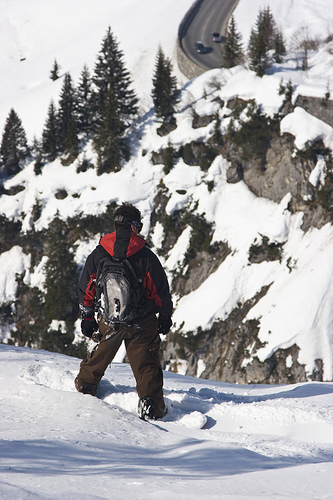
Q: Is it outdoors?
A: Yes, it is outdoors.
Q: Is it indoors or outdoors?
A: It is outdoors.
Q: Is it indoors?
A: No, it is outdoors.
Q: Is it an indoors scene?
A: No, it is outdoors.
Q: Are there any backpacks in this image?
A: Yes, there is a backpack.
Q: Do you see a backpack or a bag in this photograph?
A: Yes, there is a backpack.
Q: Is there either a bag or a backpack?
A: Yes, there is a backpack.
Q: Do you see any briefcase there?
A: No, there are no briefcases.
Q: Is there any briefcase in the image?
A: No, there are no briefcases.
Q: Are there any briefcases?
A: No, there are no briefcases.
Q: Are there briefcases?
A: No, there are no briefcases.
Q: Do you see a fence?
A: No, there are no fences.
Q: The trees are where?
A: The trees are on the mountain.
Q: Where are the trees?
A: The trees are on the mountain.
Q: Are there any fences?
A: No, there are no fences.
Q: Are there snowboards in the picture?
A: Yes, there is a snowboard.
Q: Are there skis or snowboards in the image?
A: Yes, there is a snowboard.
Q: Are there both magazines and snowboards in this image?
A: No, there is a snowboard but no magazines.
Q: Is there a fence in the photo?
A: No, there are no fences.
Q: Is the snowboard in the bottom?
A: Yes, the snowboard is in the bottom of the image.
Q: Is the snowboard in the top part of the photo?
A: No, the snowboard is in the bottom of the image.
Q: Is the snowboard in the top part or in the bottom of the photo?
A: The snowboard is in the bottom of the image.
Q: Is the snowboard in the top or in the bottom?
A: The snowboard is in the bottom of the image.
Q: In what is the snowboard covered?
A: The snowboard is covered in snow.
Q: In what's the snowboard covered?
A: The snowboard is covered in snow.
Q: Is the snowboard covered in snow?
A: Yes, the snowboard is covered in snow.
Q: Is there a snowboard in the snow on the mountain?
A: Yes, there is a snowboard in the snow.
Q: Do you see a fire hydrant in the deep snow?
A: No, there is a snowboard in the snow.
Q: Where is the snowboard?
A: The snowboard is on the snow.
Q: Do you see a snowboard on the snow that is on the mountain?
A: Yes, there is a snowboard on the snow.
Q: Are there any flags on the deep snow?
A: No, there is a snowboard on the snow.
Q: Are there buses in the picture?
A: No, there are no buses.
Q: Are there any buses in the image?
A: No, there are no buses.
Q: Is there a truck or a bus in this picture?
A: No, there are no buses or trucks.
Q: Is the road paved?
A: Yes, the road is paved.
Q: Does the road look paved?
A: Yes, the road is paved.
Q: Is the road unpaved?
A: No, the road is paved.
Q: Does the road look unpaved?
A: No, the road is paved.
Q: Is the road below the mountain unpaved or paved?
A: The road is paved.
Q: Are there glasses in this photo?
A: No, there are no glasses.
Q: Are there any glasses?
A: No, there are no glasses.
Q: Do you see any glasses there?
A: No, there are no glasses.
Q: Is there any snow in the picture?
A: Yes, there is snow.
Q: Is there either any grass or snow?
A: Yes, there is snow.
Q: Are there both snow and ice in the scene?
A: No, there is snow but no ice.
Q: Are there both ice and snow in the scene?
A: No, there is snow but no ice.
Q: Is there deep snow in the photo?
A: Yes, there is deep snow.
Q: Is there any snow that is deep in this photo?
A: Yes, there is deep snow.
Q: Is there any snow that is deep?
A: Yes, there is snow that is deep.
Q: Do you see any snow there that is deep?
A: Yes, there is snow that is deep.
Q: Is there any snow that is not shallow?
A: Yes, there is deep snow.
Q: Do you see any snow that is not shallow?
A: Yes, there is deep snow.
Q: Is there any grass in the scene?
A: No, there is no grass.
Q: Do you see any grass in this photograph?
A: No, there is no grass.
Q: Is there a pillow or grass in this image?
A: No, there are no grass or pillows.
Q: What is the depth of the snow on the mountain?
A: The snow is deep.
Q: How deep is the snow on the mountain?
A: The snow is deep.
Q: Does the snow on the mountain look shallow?
A: No, the snow is deep.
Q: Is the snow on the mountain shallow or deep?
A: The snow is deep.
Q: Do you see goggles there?
A: Yes, there are goggles.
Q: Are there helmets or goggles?
A: Yes, there are goggles.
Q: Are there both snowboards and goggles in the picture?
A: Yes, there are both goggles and a snowboard.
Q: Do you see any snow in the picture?
A: Yes, there is snow.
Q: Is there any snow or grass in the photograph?
A: Yes, there is snow.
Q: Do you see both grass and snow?
A: No, there is snow but no grass.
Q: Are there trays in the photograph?
A: No, there are no trays.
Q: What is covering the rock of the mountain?
A: The snow is covering the rock.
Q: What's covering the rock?
A: The snow is covering the rock.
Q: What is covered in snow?
A: The mountain is covered in snow.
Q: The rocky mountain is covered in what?
A: The mountain is covered in snow.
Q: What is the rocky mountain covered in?
A: The mountain is covered in snow.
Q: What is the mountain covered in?
A: The mountain is covered in snow.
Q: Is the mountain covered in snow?
A: Yes, the mountain is covered in snow.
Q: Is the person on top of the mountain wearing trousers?
A: Yes, the person is wearing trousers.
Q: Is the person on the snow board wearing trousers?
A: Yes, the person is wearing trousers.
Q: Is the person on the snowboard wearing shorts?
A: No, the person is wearing trousers.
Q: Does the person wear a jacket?
A: Yes, the person wears a jacket.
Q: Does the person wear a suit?
A: No, the person wears a jacket.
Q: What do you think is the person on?
A: The person is on the snowboard.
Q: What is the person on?
A: The person is on the snowboard.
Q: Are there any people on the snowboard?
A: Yes, there is a person on the snowboard.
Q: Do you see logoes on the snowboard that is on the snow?
A: No, there is a person on the snow board.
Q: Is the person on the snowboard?
A: Yes, the person is on the snowboard.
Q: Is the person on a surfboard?
A: No, the person is on the snowboard.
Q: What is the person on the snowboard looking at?
A: The person is looking at the mountain.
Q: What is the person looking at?
A: The person is looking at the mountain.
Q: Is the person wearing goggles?
A: Yes, the person is wearing goggles.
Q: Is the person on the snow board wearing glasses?
A: No, the person is wearing goggles.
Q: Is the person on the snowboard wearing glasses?
A: No, the person is wearing goggles.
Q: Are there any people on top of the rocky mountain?
A: Yes, there is a person on top of the mountain.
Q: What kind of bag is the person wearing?
A: The person is wearing a backpack.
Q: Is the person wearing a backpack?
A: Yes, the person is wearing a backpack.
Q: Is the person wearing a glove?
A: Yes, the person is wearing a glove.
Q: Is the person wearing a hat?
A: No, the person is wearing a glove.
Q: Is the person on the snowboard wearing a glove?
A: Yes, the person is wearing a glove.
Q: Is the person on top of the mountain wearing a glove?
A: Yes, the person is wearing a glove.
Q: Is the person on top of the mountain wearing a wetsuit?
A: No, the person is wearing a glove.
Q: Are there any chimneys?
A: No, there are no chimneys.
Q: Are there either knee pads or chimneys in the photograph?
A: No, there are no chimneys or knee pads.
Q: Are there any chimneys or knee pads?
A: No, there are no chimneys or knee pads.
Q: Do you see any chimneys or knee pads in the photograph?
A: No, there are no chimneys or knee pads.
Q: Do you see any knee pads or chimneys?
A: No, there are no chimneys or knee pads.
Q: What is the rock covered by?
A: The rock is covered by the snow.